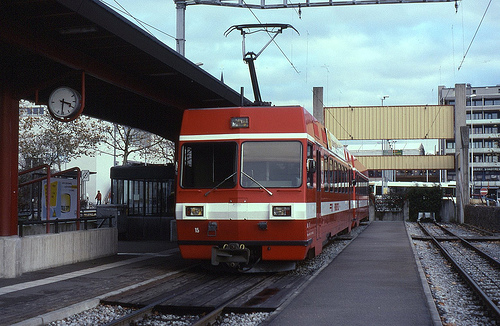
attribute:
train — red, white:
[170, 106, 371, 277]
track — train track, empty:
[107, 274, 268, 324]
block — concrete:
[1, 237, 18, 279]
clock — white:
[48, 85, 80, 122]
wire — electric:
[243, 0, 260, 23]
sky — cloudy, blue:
[100, 3, 499, 115]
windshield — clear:
[241, 140, 304, 190]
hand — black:
[60, 99, 65, 117]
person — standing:
[94, 190, 103, 207]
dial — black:
[71, 99, 78, 104]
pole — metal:
[174, 0, 186, 53]